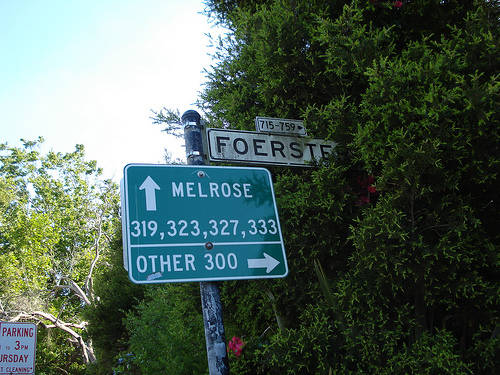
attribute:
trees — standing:
[116, 2, 497, 374]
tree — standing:
[1, 139, 126, 364]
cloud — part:
[34, 43, 162, 138]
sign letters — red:
[0, 310, 43, 373]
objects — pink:
[361, 174, 381, 197]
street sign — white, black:
[204, 119, 339, 164]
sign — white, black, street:
[253, 111, 308, 138]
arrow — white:
[132, 170, 160, 214]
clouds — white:
[80, 49, 155, 154]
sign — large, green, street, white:
[119, 160, 295, 294]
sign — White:
[206, 107, 357, 172]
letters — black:
[216, 132, 330, 159]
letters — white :
[213, 130, 338, 164]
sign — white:
[202, 107, 346, 179]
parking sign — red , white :
[0, 317, 36, 371]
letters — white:
[171, 177, 255, 197]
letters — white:
[171, 180, 186, 200]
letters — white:
[185, 181, 195, 198]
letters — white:
[196, 180, 210, 198]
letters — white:
[207, 181, 221, 198]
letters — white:
[219, 182, 233, 199]